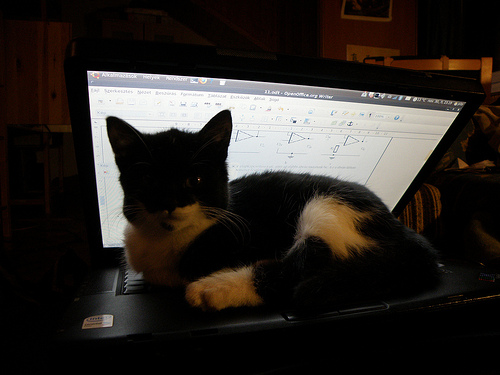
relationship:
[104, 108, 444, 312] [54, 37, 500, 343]
animal sitting on computer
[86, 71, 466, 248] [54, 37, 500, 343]
screen on computer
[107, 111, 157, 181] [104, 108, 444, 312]
ear on animal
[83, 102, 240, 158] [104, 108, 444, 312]
ear on animal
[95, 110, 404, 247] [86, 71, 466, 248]
program on screen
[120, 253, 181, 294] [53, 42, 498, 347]
keyboard on computer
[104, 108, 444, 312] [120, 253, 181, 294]
animal sitting on keyboard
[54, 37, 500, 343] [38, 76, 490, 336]
computer has intel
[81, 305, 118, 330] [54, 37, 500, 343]
sticker on computer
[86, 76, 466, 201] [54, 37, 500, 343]
screen on computer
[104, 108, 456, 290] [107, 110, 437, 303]
animal has fur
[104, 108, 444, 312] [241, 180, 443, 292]
animal has hair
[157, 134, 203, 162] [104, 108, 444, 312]
hair on animal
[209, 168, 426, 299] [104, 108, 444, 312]
hair on animal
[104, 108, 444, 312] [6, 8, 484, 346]
animal in room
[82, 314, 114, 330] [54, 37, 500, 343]
sticker on computer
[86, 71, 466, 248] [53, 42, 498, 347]
screen on computer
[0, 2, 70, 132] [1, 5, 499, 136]
wood panels on wall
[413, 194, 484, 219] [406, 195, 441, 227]
portion of bedspread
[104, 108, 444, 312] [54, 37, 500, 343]
animal on computer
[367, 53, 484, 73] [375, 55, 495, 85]
wood from furniture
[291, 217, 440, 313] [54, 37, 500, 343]
cat tail on computer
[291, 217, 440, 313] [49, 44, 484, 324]
cat tail on laptop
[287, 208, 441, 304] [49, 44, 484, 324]
cat tail on laptop